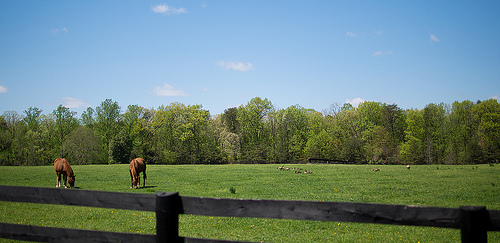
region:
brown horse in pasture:
[127, 151, 173, 184]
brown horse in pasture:
[41, 159, 96, 199]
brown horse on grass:
[110, 154, 194, 199]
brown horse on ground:
[39, 154, 98, 191]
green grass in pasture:
[202, 157, 380, 241]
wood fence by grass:
[209, 175, 344, 214]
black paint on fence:
[205, 192, 312, 241]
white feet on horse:
[55, 179, 80, 194]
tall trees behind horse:
[147, 95, 337, 177]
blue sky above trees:
[91, 7, 177, 48]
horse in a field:
[125, 151, 157, 191]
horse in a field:
[45, 153, 85, 193]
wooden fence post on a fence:
[146, 188, 186, 241]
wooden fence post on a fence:
[455, 198, 492, 242]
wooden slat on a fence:
[176, 189, 473, 234]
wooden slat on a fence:
[0, 178, 157, 215]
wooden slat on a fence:
[2, 216, 159, 241]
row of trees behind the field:
[0, 90, 498, 168]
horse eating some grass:
[122, 148, 150, 191]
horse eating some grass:
[47, 153, 76, 189]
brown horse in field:
[112, 148, 147, 188]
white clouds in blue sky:
[25, 32, 75, 82]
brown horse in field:
[41, 151, 81, 191]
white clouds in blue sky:
[116, 29, 162, 63]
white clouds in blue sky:
[247, 29, 289, 69]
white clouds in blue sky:
[323, 48, 377, 83]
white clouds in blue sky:
[436, 10, 481, 58]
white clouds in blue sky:
[299, 40, 343, 78]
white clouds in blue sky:
[209, 36, 250, 68]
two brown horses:
[51, 155, 144, 188]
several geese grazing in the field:
[275, 160, 410, 175]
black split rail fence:
[0, 185, 485, 240]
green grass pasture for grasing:
[2, 165, 492, 240]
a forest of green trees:
[5, 96, 491, 163]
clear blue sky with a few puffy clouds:
[0, 1, 495, 107]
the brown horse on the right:
[126, 155, 147, 188]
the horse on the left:
[50, 160, 70, 185]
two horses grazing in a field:
[55, 155, 146, 190]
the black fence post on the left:
[152, 191, 178, 240]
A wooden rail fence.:
[0, 183, 499, 242]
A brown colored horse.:
[127, 156, 149, 190]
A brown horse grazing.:
[51, 153, 78, 190]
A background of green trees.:
[0, 93, 499, 166]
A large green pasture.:
[0, 163, 499, 214]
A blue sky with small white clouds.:
[0, 0, 499, 124]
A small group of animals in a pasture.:
[274, 162, 314, 177]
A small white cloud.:
[215, 58, 255, 73]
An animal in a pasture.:
[371, 165, 382, 173]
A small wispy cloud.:
[42, 24, 73, 39]